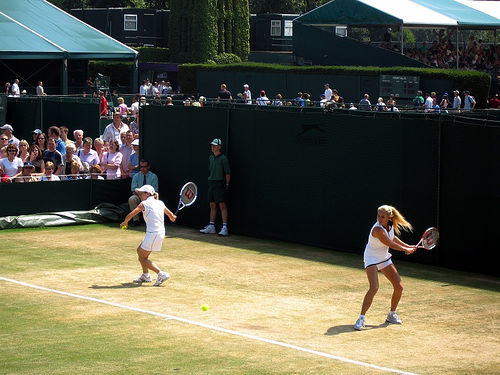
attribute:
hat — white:
[132, 182, 159, 194]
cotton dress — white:
[362, 219, 399, 276]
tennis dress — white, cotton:
[361, 220, 398, 270]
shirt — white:
[135, 197, 173, 229]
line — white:
[105, 297, 312, 358]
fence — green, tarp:
[261, 132, 351, 192]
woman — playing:
[123, 172, 195, 287]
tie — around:
[138, 174, 148, 186]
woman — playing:
[343, 203, 410, 329]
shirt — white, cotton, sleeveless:
[141, 196, 167, 233]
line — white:
[42, 277, 418, 370]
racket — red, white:
[408, 225, 440, 250]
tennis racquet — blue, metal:
[171, 177, 206, 226]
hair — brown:
[392, 209, 415, 241]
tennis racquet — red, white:
[405, 224, 440, 254]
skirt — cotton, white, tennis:
[137, 229, 164, 249]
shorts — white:
[144, 234, 165, 254]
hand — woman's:
[403, 239, 420, 256]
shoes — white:
[353, 315, 366, 331]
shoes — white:
[383, 311, 402, 324]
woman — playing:
[117, 182, 179, 289]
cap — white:
[131, 179, 159, 198]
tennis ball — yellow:
[198, 303, 211, 310]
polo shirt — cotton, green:
[205, 151, 231, 183]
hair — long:
[376, 200, 418, 238]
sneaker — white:
[216, 221, 228, 236]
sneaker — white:
[193, 220, 217, 235]